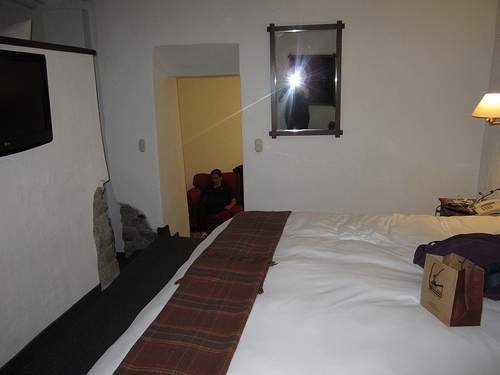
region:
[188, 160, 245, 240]
man sitting on red couch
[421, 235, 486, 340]
brown shopping bag on bed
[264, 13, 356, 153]
mirror on wall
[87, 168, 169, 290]
walls with exposed brick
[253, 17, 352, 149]
person taking picture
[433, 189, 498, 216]
phone on table by bed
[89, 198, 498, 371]
folded up blanket on bed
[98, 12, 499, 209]
white painted walls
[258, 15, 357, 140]
person reflected in mirror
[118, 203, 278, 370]
red plaid blanket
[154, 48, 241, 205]
the door is open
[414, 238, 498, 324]
shopping bag on the bed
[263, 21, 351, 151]
a mirror on the wall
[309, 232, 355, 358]
the bedcover is white in colour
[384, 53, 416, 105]
the wall is white in color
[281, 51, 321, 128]
an image of a person is on the mirror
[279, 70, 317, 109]
the person is shining something on the mirror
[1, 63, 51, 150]
a television screen is on the wall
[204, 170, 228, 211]
a man is seated on the couch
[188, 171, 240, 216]
the couch is red in colour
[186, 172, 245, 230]
A red sofa.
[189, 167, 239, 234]
A man sitting down.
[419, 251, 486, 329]
A paper shopping bag with handles.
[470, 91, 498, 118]
A white lampshade.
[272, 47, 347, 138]
A mirror.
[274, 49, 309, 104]
A flash from a camera.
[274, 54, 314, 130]
A reflection of a person taking a picture.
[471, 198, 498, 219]
A white telephone.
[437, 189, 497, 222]
A nightstand.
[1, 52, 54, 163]
A black flat screen television.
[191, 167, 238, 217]
the person is sitted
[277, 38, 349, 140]
the mans reflection is in the mirror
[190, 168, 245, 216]
the soofa is red in color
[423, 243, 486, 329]
the bag is brown in color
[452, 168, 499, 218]
the telehone is on the dsk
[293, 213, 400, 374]
the comforter is white in color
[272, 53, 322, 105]
light is shining in the mirror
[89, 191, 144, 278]
the wall is cracked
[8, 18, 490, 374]
the room is the bedroom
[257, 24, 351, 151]
the frame of the mirror is wooden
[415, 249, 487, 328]
straw shopping bag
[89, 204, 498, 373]
double bed with white cover and brown foot coverlet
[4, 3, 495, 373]
inexpensive hotel room with white and cream colored walls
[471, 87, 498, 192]
bedside lamp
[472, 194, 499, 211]
telephone on bedside table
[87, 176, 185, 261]
damaged walls in hotel room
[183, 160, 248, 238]
two persons on a sofa in another room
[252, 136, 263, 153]
electrical wall switch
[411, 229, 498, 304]
small dark colored suitcase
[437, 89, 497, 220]
bedside table with lamp and phone